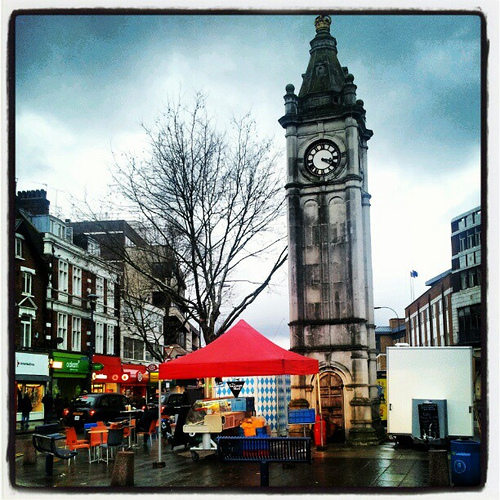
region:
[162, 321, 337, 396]
the tent is red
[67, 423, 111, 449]
the seatds are orange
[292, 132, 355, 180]
the clock says 3.30pm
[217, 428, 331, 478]
the bench is metallic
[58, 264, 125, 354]
the windows are on the building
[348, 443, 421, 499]
the floor is wet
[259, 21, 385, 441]
the uilding is tall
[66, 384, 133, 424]
the car is black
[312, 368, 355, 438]
the door is arched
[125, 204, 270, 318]
the branch has no leaves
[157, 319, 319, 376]
The tent is red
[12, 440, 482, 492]
The ground is wet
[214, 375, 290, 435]
The box is white and blue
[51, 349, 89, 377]
The sign is green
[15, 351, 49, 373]
The sign is white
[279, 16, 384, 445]
A large clock tower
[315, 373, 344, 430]
The door is brown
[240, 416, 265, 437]
The boxes are orange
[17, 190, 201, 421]
A row of buildings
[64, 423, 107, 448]
The chairs are orange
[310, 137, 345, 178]
black and whtie clock in tower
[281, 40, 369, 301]
gray clock tower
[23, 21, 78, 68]
white clouds in blue sky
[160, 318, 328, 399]
red tent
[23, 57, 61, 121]
white clouds in blue sky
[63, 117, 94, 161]
white clouds in blue sky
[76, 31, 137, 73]
white clouds in blue sky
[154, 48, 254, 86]
white clouds in blue sky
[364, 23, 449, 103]
white clouds in blue sky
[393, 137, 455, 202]
white clouds in blue sky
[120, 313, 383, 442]
the tent is red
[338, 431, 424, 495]
the pavement is wet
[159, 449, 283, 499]
the pavement is wet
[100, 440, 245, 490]
the pavement is wet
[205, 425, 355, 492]
the pavement is wet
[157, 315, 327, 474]
TENT IS IN FRONT OF TOWER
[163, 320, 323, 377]
TENT HAS A RED COVER ON IT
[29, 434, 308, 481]
TWO BENCHES IN THE FORE GROUND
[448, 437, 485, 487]
GARBAGE CAN IS BLUE IN COLOR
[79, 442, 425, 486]
GROUND IS WET DUE TO RAIN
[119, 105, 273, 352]
TREE HAS NO LEAVES ON IT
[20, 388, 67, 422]
PEOPLE ARE WALKING ON THE SIDE WALK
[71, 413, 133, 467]
CHAIRS ARE AROUND A TABLE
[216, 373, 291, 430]
WHITE AND BLUE DIAMOND WALL IS BEHIND TENT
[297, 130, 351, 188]
CLOCK ON TOWER READS 3:20